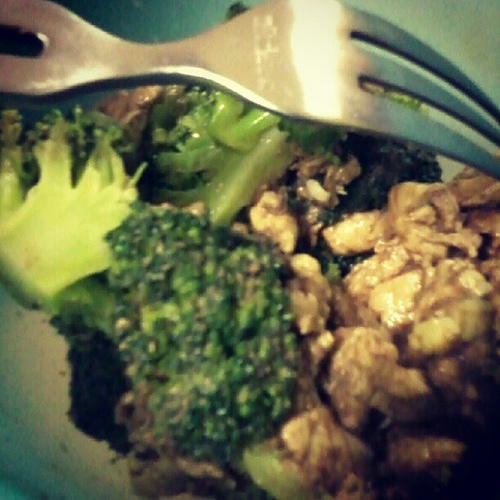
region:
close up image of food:
[13, 15, 490, 495]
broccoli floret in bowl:
[96, 193, 310, 465]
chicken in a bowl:
[344, 225, 470, 484]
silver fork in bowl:
[236, 3, 461, 150]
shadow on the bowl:
[68, 333, 126, 443]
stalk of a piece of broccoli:
[11, 163, 94, 308]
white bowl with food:
[7, 332, 58, 473]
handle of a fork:
[6, 3, 103, 118]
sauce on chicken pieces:
[412, 283, 462, 313]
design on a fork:
[3, 13, 58, 73]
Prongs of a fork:
[343, 1, 499, 182]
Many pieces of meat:
[258, 167, 498, 498]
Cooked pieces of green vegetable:
[2, 91, 307, 458]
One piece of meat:
[246, 184, 302, 254]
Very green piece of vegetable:
[103, 200, 306, 462]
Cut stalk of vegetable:
[0, 146, 141, 306]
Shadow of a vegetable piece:
[48, 308, 136, 463]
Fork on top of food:
[0, 0, 499, 182]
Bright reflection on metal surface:
[281, 1, 363, 133]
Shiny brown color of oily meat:
[286, 179, 498, 499]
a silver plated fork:
[0, 0, 498, 182]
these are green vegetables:
[0, 90, 295, 456]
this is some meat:
[245, 151, 499, 498]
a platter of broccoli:
[5, 88, 445, 496]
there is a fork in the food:
[0, 0, 497, 182]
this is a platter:
[1, 298, 136, 499]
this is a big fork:
[0, 0, 498, 178]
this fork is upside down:
[2, 0, 498, 182]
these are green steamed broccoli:
[0, 80, 449, 499]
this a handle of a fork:
[0, 0, 150, 101]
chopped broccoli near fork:
[120, 281, 264, 432]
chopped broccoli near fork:
[20, 146, 121, 285]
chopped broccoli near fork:
[161, 94, 275, 201]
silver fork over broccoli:
[22, 18, 497, 182]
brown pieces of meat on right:
[322, 195, 418, 241]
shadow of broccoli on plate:
[69, 337, 148, 449]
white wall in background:
[443, 9, 490, 49]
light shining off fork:
[273, 1, 362, 104]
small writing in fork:
[241, 16, 286, 99]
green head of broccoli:
[119, 219, 296, 460]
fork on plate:
[0, 1, 498, 176]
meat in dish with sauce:
[382, 193, 476, 379]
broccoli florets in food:
[127, 316, 290, 446]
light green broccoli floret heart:
[37, 202, 97, 264]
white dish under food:
[4, 316, 53, 473]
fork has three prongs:
[346, 7, 498, 170]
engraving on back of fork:
[249, 14, 289, 96]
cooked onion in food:
[385, 178, 435, 228]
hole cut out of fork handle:
[2, 19, 51, 64]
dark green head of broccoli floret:
[138, 266, 233, 376]